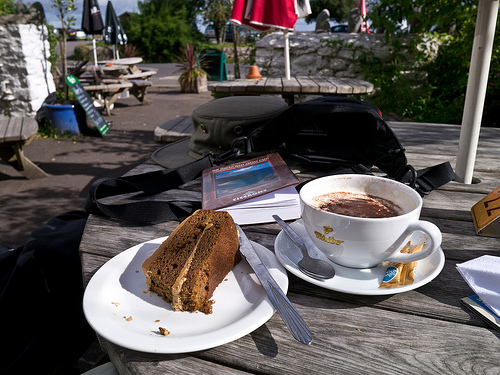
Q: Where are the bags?
A: On table.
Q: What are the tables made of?
A: Wood.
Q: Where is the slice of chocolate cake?
A: On white plate.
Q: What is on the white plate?
A: A piece of cake.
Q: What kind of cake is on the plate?
A: Chocolate.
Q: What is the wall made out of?
A: Stone.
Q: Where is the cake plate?
A: On the table.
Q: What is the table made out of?
A: Weathered wood.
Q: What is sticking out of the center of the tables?
A: Umbrella.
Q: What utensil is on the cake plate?
A: A knife.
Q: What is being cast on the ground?
A: Shadows.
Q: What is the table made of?
A: Wood.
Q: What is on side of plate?
A: Knife.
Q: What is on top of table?
A: Cup and saucer.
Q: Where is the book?
A: On table.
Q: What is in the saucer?
A: Chocolate cake.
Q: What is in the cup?
A: Cup with coffee.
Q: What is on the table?
A: Black bag.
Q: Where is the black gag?
A: Wooden table.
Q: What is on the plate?
A: Cake.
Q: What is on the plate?
A: Food.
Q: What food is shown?
A: Cake.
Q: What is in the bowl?
A: Pudding.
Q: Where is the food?
A: On the table.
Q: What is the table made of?
A: Wood.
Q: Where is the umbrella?
A: Above the table.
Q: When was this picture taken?
A: Daytime.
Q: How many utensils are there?
A: 2.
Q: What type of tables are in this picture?
A: Wooden.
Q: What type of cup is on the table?
A: Coffee cup.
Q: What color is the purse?
A: Black.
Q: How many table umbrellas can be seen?
A: 3.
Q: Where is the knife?
A: On plate.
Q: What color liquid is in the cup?
A: Brown.